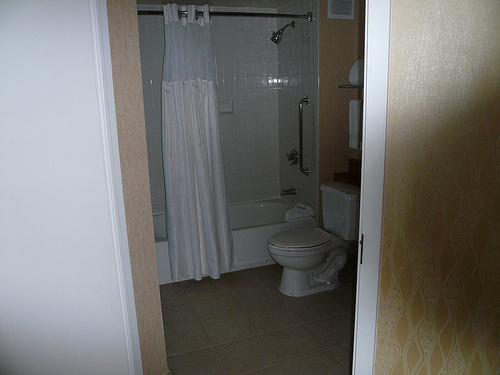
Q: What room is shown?
A: Bathroom.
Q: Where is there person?
A: Taking photo.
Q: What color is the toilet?
A: White.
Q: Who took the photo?
A: Homeowner.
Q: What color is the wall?
A: Tan.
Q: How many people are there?
A: Zero.